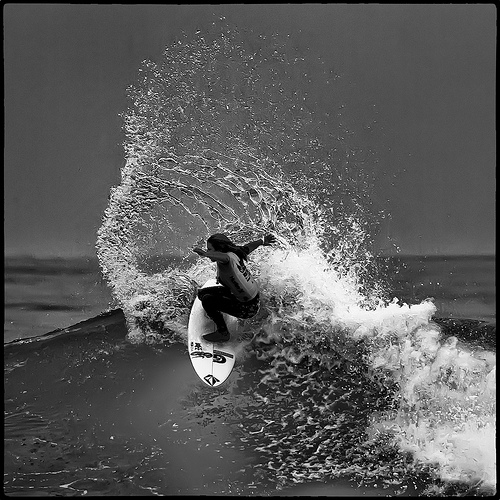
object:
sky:
[349, 8, 473, 100]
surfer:
[191, 229, 276, 341]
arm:
[238, 232, 275, 259]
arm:
[192, 237, 230, 264]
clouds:
[380, 64, 497, 185]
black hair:
[206, 233, 250, 264]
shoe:
[202, 327, 230, 343]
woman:
[192, 231, 277, 343]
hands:
[193, 238, 210, 257]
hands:
[260, 233, 278, 247]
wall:
[182, 88, 253, 155]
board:
[187, 275, 239, 388]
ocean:
[358, 233, 449, 396]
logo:
[235, 258, 251, 282]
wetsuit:
[197, 249, 261, 343]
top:
[217, 247, 266, 305]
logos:
[212, 349, 234, 364]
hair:
[216, 237, 229, 249]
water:
[176, 380, 319, 437]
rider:
[192, 233, 277, 343]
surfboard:
[183, 262, 243, 392]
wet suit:
[192, 232, 277, 343]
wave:
[266, 257, 409, 375]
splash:
[168, 63, 303, 196]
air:
[349, 90, 438, 157]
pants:
[198, 285, 261, 343]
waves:
[296, 285, 496, 496]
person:
[192, 232, 279, 342]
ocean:
[1, 395, 147, 496]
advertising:
[235, 257, 251, 283]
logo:
[203, 374, 220, 387]